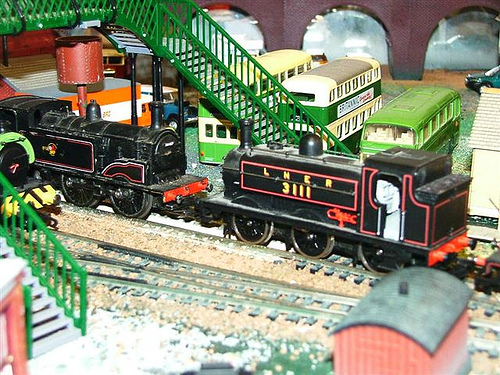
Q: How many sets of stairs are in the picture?
A: Two.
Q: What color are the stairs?
A: Green.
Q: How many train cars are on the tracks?
A: Three.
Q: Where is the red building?
A: In the front.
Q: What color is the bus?
A: Green.